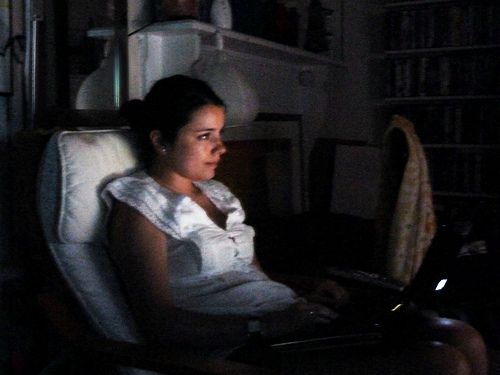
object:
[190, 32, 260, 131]
lamp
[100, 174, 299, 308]
blouse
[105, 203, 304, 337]
arm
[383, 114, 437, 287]
blanket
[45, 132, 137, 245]
pillow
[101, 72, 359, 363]
woman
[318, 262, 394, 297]
remote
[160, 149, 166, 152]
earring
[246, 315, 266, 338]
black watch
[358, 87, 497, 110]
shelf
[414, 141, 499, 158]
shelf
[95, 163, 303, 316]
shirt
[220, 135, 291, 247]
fireplace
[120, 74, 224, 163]
hair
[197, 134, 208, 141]
eye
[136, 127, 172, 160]
jam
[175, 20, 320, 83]
shelf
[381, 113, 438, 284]
chair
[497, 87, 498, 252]
tv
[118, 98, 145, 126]
ponytail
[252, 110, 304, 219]
frame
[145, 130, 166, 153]
ear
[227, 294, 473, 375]
lap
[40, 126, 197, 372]
chair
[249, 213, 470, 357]
computer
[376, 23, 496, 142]
books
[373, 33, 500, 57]
shelves